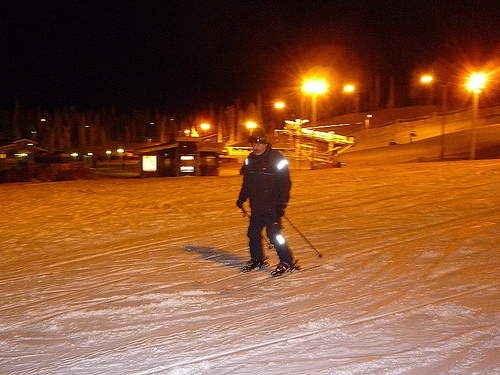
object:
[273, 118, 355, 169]
machine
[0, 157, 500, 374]
field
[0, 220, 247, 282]
tracks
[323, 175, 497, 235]
tracks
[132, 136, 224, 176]
building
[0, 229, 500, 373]
ski prints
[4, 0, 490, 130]
sky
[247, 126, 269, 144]
hat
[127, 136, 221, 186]
shed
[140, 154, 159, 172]
windows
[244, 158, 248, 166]
reflective material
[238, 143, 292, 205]
jacket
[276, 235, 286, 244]
bright light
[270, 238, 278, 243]
knee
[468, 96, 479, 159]
pole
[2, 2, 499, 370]
photo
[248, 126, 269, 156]
head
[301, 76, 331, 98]
lights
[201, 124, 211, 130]
lights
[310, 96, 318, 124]
pole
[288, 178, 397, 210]
tracks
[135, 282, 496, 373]
tracks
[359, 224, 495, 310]
tracks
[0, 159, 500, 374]
snow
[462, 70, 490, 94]
light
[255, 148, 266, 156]
beard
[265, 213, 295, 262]
legs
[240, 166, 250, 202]
arm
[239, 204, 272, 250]
sticks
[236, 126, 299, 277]
man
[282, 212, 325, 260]
poles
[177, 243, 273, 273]
shadow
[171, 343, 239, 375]
white snow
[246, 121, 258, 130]
lights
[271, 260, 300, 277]
boots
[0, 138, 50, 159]
building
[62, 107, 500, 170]
street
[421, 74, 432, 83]
light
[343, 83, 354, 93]
light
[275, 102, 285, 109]
light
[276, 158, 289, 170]
light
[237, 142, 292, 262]
cloths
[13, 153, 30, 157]
window